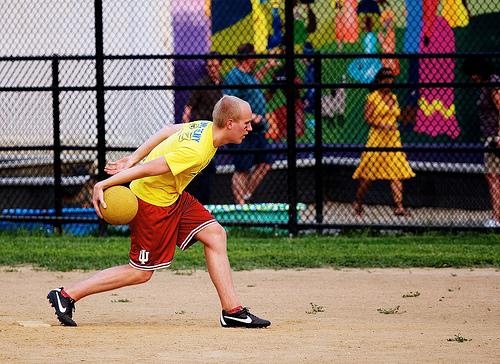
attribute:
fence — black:
[0, 0, 498, 239]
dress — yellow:
[348, 91, 420, 182]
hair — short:
[208, 91, 242, 121]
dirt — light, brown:
[0, 260, 497, 362]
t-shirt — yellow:
[128, 121, 218, 206]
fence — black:
[244, 20, 498, 240]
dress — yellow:
[354, 90, 414, 182]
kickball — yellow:
[98, 185, 138, 224]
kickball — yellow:
[68, 155, 164, 272]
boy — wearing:
[139, 84, 265, 217]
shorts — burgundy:
[122, 181, 212, 262]